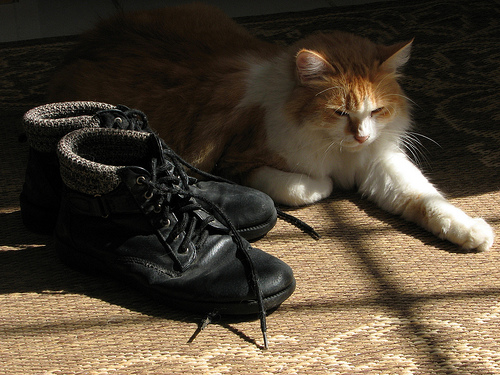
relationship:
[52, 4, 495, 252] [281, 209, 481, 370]
cat laying on floor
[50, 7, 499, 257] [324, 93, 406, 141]
cat closing eyes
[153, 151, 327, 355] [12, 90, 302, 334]
laces on shoes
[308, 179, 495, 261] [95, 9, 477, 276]
paws on cat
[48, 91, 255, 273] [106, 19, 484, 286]
pair boots near cat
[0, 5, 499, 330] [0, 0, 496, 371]
shadow on carpet